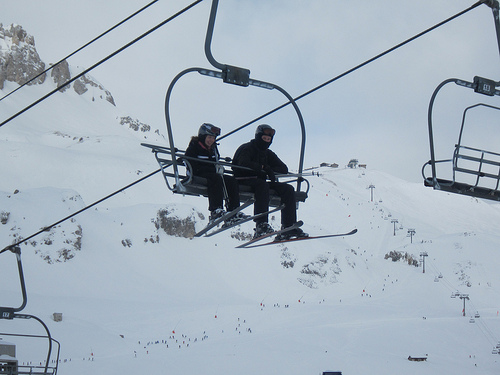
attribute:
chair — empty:
[421, 58, 498, 188]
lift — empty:
[417, 72, 497, 202]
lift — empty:
[414, 55, 499, 197]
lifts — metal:
[131, 70, 485, 227]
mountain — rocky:
[1, 22, 496, 373]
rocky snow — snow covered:
[5, 5, 452, 367]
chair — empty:
[1, 302, 60, 374]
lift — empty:
[2, 245, 60, 374]